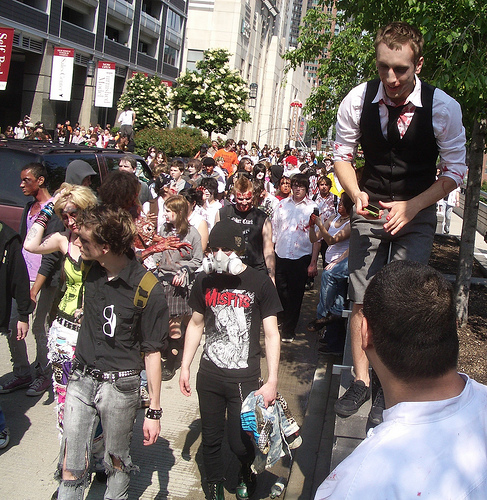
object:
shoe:
[334, 380, 371, 417]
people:
[0, 165, 54, 397]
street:
[1, 253, 348, 497]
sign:
[48, 46, 74, 102]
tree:
[274, 1, 485, 298]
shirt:
[331, 73, 468, 206]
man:
[332, 26, 468, 415]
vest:
[359, 78, 440, 208]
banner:
[0, 26, 16, 91]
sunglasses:
[101, 304, 117, 338]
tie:
[376, 99, 413, 148]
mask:
[201, 248, 242, 275]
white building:
[175, 0, 349, 150]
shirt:
[57, 232, 89, 323]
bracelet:
[144, 408, 164, 421]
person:
[268, 173, 324, 343]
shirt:
[271, 194, 323, 259]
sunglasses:
[238, 195, 254, 202]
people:
[29, 158, 96, 404]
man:
[57, 203, 173, 496]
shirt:
[74, 249, 170, 374]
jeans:
[52, 369, 142, 498]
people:
[178, 219, 285, 497]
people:
[23, 185, 99, 497]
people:
[143, 190, 204, 380]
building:
[0, 1, 190, 132]